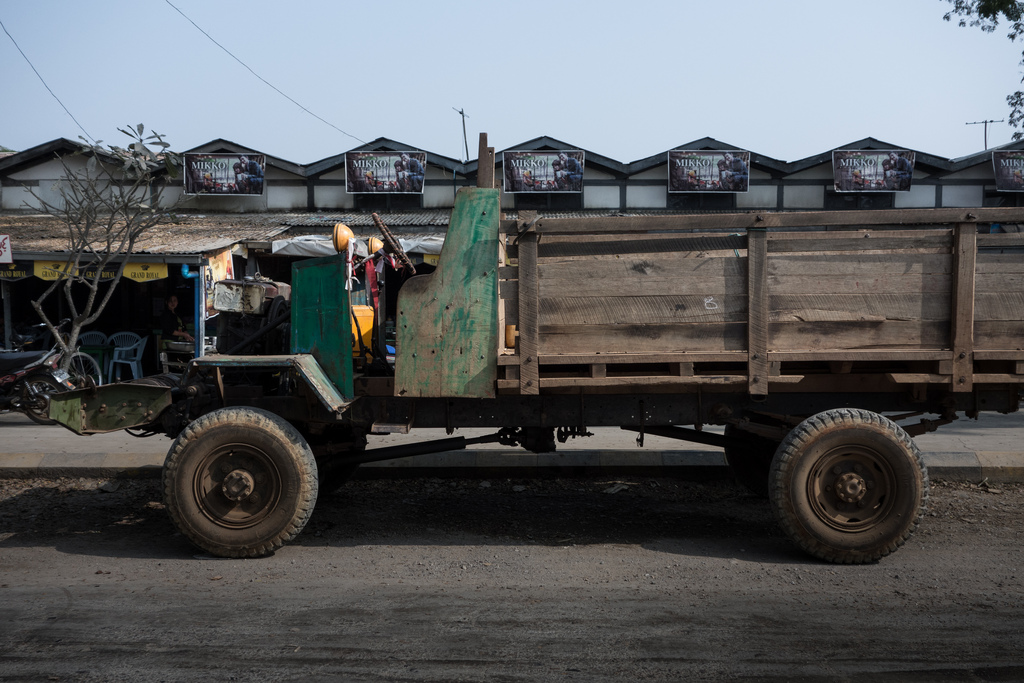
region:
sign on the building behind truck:
[172, 147, 262, 193]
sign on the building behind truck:
[334, 143, 415, 189]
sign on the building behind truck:
[492, 143, 584, 189]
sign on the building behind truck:
[659, 140, 746, 189]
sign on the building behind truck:
[983, 140, 1019, 191]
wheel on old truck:
[159, 405, 318, 561]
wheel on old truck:
[765, 404, 931, 569]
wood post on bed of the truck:
[514, 208, 541, 404]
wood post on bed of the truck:
[743, 208, 767, 398]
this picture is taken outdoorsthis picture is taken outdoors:
[347, 614, 383, 621]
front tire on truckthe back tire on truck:
[724, 392, 978, 569]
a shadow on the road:
[15, 451, 148, 570]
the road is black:
[503, 574, 770, 674]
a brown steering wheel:
[363, 192, 427, 291]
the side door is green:
[386, 162, 516, 412]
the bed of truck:
[508, 187, 995, 428]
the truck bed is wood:
[489, 184, 1005, 415]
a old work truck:
[13, 168, 1007, 581]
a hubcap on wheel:
[215, 454, 280, 511]